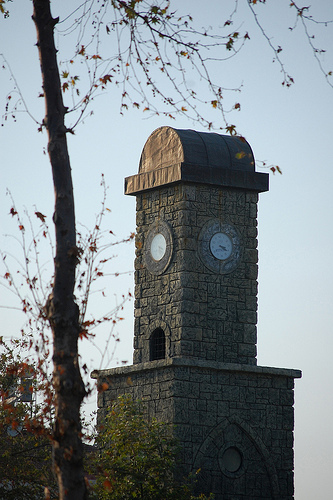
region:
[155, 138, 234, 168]
gray and brown bricks of clock tower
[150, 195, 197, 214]
gray and brown bricks of clock tower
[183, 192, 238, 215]
gray and brown bricks of clock tower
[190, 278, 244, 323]
gray and brown bricks of clock tower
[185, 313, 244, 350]
gray and brown bricks of clock tower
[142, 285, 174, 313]
gray and brown bricks of clock tower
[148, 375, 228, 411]
gray and brown bricks of clock tower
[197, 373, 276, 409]
gray and brown bricks of clock tower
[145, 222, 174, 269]
clock in clock tower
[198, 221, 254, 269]
clock in clock tower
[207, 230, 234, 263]
A white clock.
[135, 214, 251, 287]
Clocks on the tower.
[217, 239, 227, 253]
The hands of a clock.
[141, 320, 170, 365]
A door on the tower.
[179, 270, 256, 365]
the stone tower bricks.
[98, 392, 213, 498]
A tree by the toweer.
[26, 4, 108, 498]
A tree.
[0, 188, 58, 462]
red leaves on the branches.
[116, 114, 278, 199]
The dome of the tower.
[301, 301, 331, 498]
The sky is muggy.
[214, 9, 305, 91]
The sky is clear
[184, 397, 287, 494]
The building has an arch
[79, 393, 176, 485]
The leaves are green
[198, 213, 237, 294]
The clock is round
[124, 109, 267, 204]
The top of the building is round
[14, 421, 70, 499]
The tree is in the back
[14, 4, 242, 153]
The tree has some leaves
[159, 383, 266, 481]
The building is made of stone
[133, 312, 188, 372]
The arch way has a gate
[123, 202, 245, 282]
The building has 2 clocks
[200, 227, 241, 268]
Clock with hands at 3:20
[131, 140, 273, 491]
A stone clock tower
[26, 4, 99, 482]
A tall narrow tree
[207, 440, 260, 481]
A round window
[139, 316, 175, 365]
Steel grate over a window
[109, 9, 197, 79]
Branches with leaves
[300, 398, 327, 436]
Blue sky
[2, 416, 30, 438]
A dish for satellite television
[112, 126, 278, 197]
A metallic roof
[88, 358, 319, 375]
A stone ledge around the perimeter of the clock tower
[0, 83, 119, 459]
tree in foreground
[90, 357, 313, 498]
base of the clock tower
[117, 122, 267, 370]
top of the clock tower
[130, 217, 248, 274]
two clock faces on the tower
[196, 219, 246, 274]
clock face on the right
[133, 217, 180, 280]
clock face on the left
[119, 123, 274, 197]
cap of the tower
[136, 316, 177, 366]
arched window on the tower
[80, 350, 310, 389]
a ledge on the tower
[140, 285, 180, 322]
stone on wall of tower